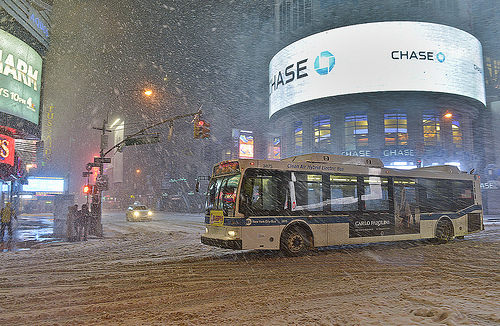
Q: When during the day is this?
A: Evening.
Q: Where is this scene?
A: City street corner.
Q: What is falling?
A: Snow.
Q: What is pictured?
A: Bus.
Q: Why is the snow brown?
A: Street slush.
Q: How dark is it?
A: Very dark.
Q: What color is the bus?
A: White.